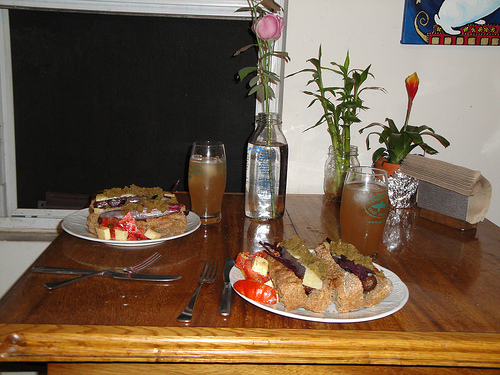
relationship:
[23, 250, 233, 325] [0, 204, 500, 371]
silverware. on a table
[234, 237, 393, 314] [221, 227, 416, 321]
dinner on a plate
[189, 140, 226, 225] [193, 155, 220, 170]
glass with ice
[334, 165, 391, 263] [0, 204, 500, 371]
glass on a table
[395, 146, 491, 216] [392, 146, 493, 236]
napkins in a holder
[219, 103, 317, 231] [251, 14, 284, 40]
vase for flower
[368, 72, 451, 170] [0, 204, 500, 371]
plant on table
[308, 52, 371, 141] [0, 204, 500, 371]
flower on table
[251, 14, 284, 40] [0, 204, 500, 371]
flower on table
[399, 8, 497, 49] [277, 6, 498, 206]
picture on wall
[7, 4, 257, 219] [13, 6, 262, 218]
window with screen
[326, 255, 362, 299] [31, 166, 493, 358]
meal on a table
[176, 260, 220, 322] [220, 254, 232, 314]
fork next to knife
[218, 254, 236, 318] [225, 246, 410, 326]
knife next to plate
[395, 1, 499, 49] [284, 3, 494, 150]
poster on wall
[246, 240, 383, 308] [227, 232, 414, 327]
dinner on plate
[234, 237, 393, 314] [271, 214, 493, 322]
dinner based meal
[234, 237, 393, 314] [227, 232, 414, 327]
dinner filling plate